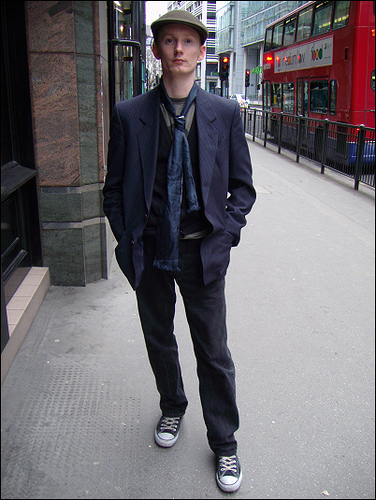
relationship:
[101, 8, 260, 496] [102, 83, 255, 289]
man wearing jacket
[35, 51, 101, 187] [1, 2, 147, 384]
block on wall of building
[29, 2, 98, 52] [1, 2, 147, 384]
block on wall of building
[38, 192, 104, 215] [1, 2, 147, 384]
block on wall of building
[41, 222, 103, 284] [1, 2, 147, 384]
block on wall of building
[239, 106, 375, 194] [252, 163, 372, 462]
railing on sidewalk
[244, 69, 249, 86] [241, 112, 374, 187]
traffic light on street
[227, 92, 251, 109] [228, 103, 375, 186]
vehicle on street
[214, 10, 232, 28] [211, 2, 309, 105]
windows on building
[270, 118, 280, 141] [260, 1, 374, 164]
tire on bus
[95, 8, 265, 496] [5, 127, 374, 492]
man on sidewalk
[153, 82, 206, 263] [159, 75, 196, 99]
scarf around neck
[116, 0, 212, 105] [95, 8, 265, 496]
head on man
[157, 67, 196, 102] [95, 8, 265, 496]
neck on man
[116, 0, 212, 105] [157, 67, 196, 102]
head on neck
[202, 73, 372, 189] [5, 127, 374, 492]
railing on sidewalk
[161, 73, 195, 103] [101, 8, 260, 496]
neck on man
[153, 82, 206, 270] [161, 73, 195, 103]
scarf on neck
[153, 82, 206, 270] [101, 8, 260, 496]
scarf on man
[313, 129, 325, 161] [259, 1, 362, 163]
tire on bus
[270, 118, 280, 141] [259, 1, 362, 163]
tire on bus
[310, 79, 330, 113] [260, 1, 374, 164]
window on bus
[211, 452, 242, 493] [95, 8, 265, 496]
sneaker on man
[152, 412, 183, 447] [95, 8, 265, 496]
sneaker on man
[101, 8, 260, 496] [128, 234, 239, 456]
man wearing pants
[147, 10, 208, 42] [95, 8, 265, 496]
green cap on man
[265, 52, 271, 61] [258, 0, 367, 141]
light on bus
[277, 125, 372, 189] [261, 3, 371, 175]
blue bottom on bus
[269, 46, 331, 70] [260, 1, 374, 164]
advertisement on bus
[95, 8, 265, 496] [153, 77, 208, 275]
man wearing scarf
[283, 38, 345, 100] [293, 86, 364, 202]
imaging and lettering on bus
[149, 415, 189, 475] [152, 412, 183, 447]
right foot with ten sneaker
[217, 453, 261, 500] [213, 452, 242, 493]
left foot with sneaker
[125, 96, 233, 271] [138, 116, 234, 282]
jacket not buttoned in front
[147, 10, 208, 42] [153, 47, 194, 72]
green cap on a guys head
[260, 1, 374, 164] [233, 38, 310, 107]
bus has two decks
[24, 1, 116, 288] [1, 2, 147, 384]
side of a building